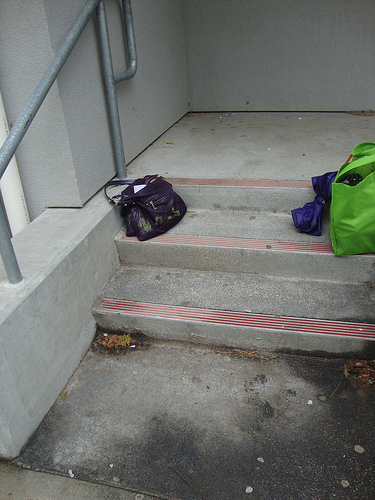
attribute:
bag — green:
[336, 173, 363, 186]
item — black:
[329, 142, 374, 256]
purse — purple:
[99, 167, 189, 243]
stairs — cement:
[91, 188, 374, 357]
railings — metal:
[45, 10, 144, 111]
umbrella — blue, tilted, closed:
[288, 155, 353, 234]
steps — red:
[93, 165, 374, 400]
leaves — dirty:
[96, 333, 132, 346]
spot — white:
[110, 473, 123, 483]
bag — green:
[304, 126, 367, 281]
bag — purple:
[92, 152, 193, 259]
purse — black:
[103, 172, 186, 239]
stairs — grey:
[97, 259, 373, 360]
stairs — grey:
[118, 174, 373, 258]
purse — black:
[104, 172, 196, 240]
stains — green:
[139, 206, 181, 226]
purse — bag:
[120, 174, 184, 241]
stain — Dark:
[273, 442, 363, 490]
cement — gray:
[122, 359, 193, 400]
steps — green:
[92, 156, 372, 363]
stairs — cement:
[209, 167, 274, 353]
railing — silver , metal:
[6, 12, 153, 227]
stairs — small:
[26, 41, 328, 380]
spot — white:
[241, 483, 259, 494]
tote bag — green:
[323, 137, 363, 263]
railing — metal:
[0, 1, 141, 288]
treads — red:
[93, 293, 362, 347]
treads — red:
[117, 220, 334, 266]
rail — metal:
[2, 8, 164, 269]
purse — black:
[92, 161, 198, 248]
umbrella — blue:
[277, 149, 349, 244]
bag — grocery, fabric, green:
[329, 135, 363, 251]